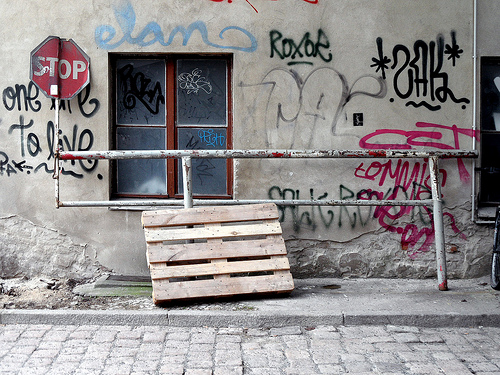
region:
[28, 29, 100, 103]
sign board is red and white in color.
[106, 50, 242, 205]
window is brown in color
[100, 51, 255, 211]
window is attached to the wall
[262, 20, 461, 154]
words are written on the wall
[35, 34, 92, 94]
sign board is stop sign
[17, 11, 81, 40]
wall is grey in color.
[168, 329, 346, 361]
floor is grey in color.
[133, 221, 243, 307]
wooden block is leaned towards the wall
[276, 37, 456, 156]
letters are black and red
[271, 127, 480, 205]
fence is leaned on the wall.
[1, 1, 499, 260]
A cement wall with graffiti.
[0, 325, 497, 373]
A white bricked street near curb.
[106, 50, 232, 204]
A four-paned window with graffiti.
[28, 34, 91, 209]
A stop sign put on top of a rail.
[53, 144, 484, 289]
A white railing leaning on the building.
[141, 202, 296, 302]
A wooden table in front of the building.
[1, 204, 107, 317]
A chipped part of the building wall.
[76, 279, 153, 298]
A green slap of concrete.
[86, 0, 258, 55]
The first blue word of graffiti on wall.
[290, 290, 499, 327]
The grayish white sidewalk in front of the building.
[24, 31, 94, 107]
Stop sign is crumpled.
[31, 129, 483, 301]
Gate is dismantled.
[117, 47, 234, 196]
Windows have graffiti on them.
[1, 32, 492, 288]
Concrete wall is dirty.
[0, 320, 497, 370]
Alleyway is bricked.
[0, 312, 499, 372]
Bricks are dry and dirty.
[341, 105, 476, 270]
Graffiti written in red.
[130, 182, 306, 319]
Pallet rest against gate.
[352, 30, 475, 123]
Graffiti written with black paint.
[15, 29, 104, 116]
Stop sign has been destroyed.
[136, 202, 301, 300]
a light brown wooden pallet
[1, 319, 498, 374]
a cobbled stone street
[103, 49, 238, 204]
a brown framed window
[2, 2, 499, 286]
a wall filled with grafitti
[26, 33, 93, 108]
a stop sign on a wall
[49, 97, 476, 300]
a metal bar leaning on a wall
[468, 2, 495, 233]
a pipe running up the wall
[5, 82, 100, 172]
the words one life to live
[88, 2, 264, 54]
blue words on the building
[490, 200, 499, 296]
a bike tire to the right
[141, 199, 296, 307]
a wooden pallet is leaning against the wall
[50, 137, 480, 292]
a metal rail is leaning against the wall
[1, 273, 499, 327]
the sidewalk is dirty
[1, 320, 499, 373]
the road is cobblestone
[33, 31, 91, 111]
the sign is red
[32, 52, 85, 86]
the sign says stop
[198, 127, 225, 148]
blue graffiti on window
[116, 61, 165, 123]
black graffiti on window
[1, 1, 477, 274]
a lot of graffiti on wall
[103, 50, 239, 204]
window in stone wall